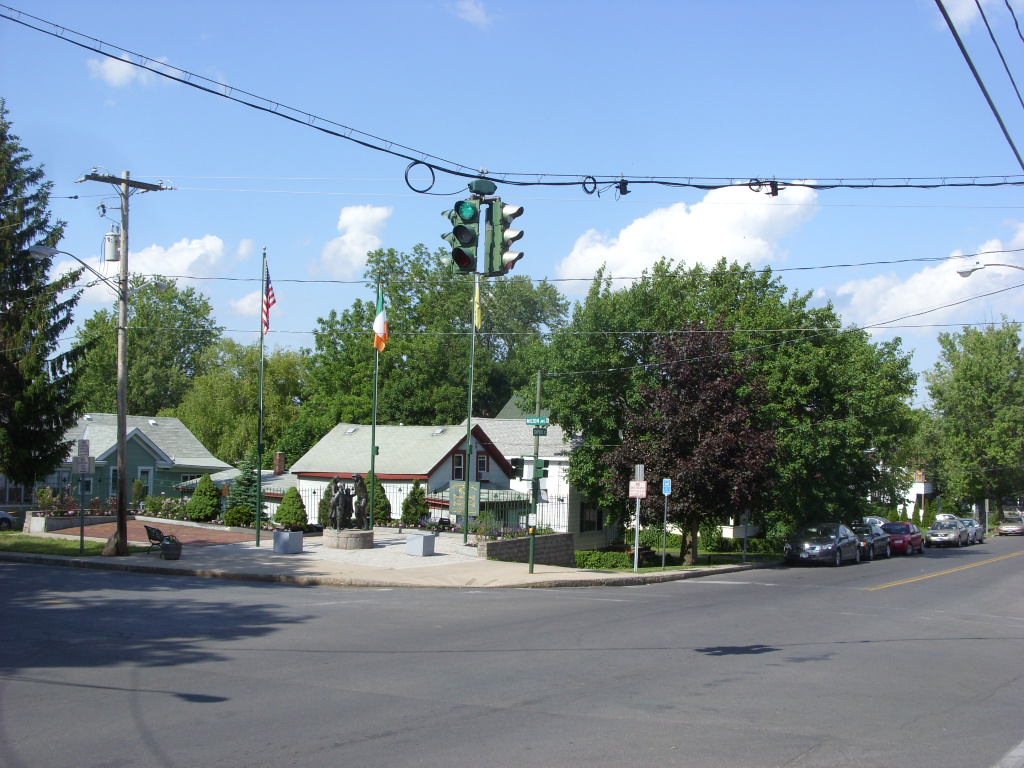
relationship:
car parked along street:
[928, 516, 968, 549] [3, 529, 1022, 765]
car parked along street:
[847, 523, 893, 561] [3, 529, 1022, 765]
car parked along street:
[793, 522, 860, 565] [3, 529, 1022, 765]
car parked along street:
[879, 519, 927, 555] [3, 529, 1022, 765]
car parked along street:
[955, 516, 988, 545] [3, 529, 1022, 765]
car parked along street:
[995, 515, 1022, 536] [3, 529, 1022, 765]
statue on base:
[326, 472, 374, 530] [322, 528, 374, 549]